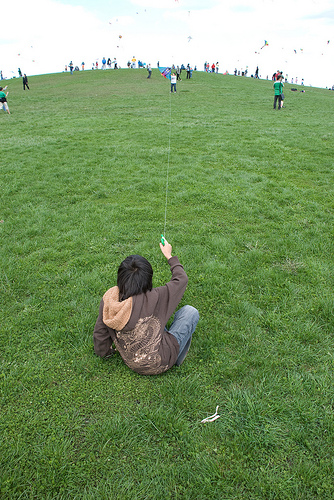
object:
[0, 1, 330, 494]
scene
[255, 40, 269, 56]
kite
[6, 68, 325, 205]
grassy knoll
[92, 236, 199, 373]
boy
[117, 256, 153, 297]
hair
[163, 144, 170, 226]
string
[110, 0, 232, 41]
sky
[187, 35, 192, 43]
flying kites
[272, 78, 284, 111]
person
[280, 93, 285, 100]
bag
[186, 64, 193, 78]
child and person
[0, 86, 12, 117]
man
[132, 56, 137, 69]
distant person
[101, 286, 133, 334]
hood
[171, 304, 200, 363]
jeans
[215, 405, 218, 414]
white string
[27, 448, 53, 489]
grass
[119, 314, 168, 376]
dragon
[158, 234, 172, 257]
hand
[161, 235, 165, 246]
something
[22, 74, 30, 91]
person in black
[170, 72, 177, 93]
person in white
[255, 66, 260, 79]
person standing